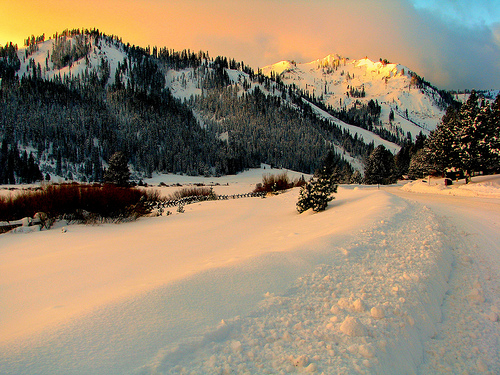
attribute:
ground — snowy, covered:
[9, 162, 498, 374]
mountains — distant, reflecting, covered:
[0, 23, 498, 189]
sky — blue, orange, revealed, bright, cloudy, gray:
[0, 1, 499, 97]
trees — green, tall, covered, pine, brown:
[1, 40, 499, 179]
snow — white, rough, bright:
[52, 43, 428, 164]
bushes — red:
[5, 178, 312, 220]